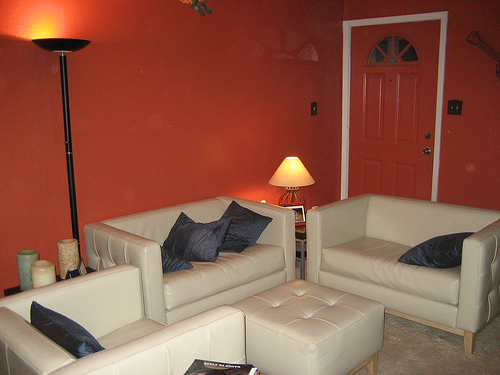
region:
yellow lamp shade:
[262, 143, 319, 193]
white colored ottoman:
[251, 278, 369, 365]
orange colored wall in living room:
[92, 73, 147, 120]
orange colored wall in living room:
[231, 65, 265, 99]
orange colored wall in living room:
[132, 139, 172, 164]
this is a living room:
[34, 12, 498, 372]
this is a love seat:
[289, 162, 489, 336]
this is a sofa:
[56, 157, 297, 321]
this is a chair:
[17, 250, 259, 372]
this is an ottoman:
[234, 251, 404, 368]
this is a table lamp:
[260, 148, 325, 227]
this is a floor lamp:
[31, 15, 106, 290]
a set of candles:
[10, 222, 95, 297]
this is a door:
[334, 5, 464, 237]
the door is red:
[333, 15, 450, 226]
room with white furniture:
[4, 3, 497, 371]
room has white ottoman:
[228, 278, 385, 372]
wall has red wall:
[1, 0, 497, 292]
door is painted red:
[346, 18, 443, 204]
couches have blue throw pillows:
[1, 191, 498, 373]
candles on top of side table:
[10, 238, 87, 295]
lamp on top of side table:
[266, 155, 318, 280]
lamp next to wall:
[32, 37, 89, 266]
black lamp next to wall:
[31, 37, 90, 269]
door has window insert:
[340, 11, 448, 201]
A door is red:
[345, 15, 440, 203]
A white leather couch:
[80, 191, 291, 326]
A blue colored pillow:
[392, 225, 477, 267]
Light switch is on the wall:
[440, 92, 465, 114]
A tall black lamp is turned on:
[25, 31, 90, 261]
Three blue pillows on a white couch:
[77, 191, 297, 322]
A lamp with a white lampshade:
[262, 151, 314, 221]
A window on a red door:
[360, 30, 417, 66]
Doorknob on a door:
[416, 136, 436, 157]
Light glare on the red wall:
[15, 12, 67, 40]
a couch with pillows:
[133, 209, 262, 311]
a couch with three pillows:
[129, 176, 307, 291]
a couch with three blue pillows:
[164, 206, 272, 311]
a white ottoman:
[249, 279, 381, 369]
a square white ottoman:
[249, 277, 399, 369]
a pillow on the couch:
[353, 206, 495, 307]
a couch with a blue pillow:
[39, 290, 228, 373]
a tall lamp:
[14, 9, 153, 288]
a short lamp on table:
[254, 133, 357, 270]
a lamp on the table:
[258, 140, 306, 239]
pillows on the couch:
[171, 205, 303, 305]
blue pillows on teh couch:
[136, 154, 290, 276]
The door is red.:
[349, 17, 441, 198]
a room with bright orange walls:
[2, 1, 498, 291]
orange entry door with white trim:
[338, 10, 452, 205]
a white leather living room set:
[0, 193, 499, 373]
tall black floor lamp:
[30, 35, 91, 269]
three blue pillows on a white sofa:
[83, 193, 297, 322]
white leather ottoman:
[228, 277, 386, 374]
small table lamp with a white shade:
[265, 154, 315, 211]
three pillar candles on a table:
[1, 235, 98, 295]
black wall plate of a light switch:
[442, 97, 464, 118]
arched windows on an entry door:
[340, 9, 444, 201]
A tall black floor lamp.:
[23, 31, 83, 270]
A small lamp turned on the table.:
[261, 154, 311, 213]